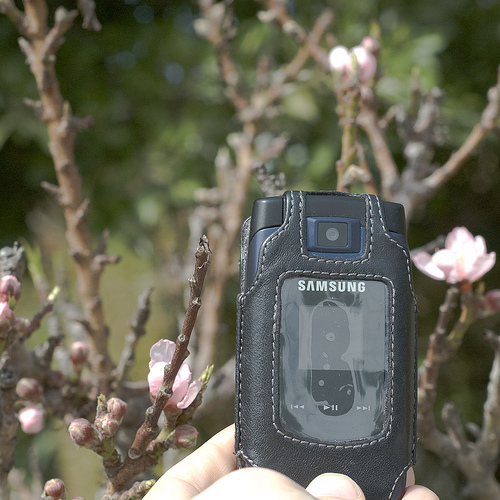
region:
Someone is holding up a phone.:
[235, 191, 416, 497]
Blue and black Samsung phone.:
[237, 190, 417, 497]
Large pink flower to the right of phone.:
[408, 226, 495, 285]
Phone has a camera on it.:
[315, 220, 350, 248]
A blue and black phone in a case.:
[235, 190, 416, 499]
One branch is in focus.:
[68, 232, 213, 499]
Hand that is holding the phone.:
[142, 422, 439, 499]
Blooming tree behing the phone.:
[5, 0, 499, 499]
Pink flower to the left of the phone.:
[147, 337, 201, 412]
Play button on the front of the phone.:
[323, 402, 336, 409]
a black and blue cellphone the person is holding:
[233, 187, 418, 485]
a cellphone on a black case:
[233, 181, 420, 498]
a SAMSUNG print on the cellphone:
[295, 278, 370, 293]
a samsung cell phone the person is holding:
[230, 185, 420, 497]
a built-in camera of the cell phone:
[313, 220, 349, 249]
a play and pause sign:
[320, 402, 340, 414]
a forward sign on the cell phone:
[353, 402, 372, 412]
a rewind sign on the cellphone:
[288, 400, 306, 412]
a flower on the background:
[143, 338, 217, 413]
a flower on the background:
[414, 230, 495, 287]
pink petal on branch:
[145, 337, 185, 403]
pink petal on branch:
[410, 225, 495, 283]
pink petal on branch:
[330, 44, 357, 76]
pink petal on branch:
[351, 35, 381, 83]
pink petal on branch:
[18, 405, 46, 433]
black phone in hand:
[136, 193, 445, 498]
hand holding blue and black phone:
[140, 192, 442, 499]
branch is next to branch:
[123, 231, 213, 452]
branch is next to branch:
[112, 283, 154, 392]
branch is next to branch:
[0, 281, 64, 383]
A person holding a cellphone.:
[251, 180, 417, 472]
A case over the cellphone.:
[231, 253, 412, 478]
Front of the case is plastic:
[277, 271, 387, 448]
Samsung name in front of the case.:
[283, 268, 369, 308]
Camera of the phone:
[298, 214, 360, 253]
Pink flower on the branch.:
[148, 349, 210, 404]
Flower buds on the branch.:
[31, 382, 119, 465]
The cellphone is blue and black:
[248, 198, 412, 288]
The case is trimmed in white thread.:
[240, 266, 416, 476]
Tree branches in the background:
[209, 20, 301, 169]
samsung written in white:
[294, 274, 373, 298]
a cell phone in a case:
[222, 176, 418, 499]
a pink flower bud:
[421, 226, 481, 288]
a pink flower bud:
[142, 325, 196, 408]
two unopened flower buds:
[57, 398, 132, 457]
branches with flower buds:
[8, 274, 107, 444]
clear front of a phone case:
[283, 286, 374, 437]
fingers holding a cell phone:
[157, 414, 446, 499]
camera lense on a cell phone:
[313, 216, 348, 249]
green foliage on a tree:
[115, 151, 180, 243]